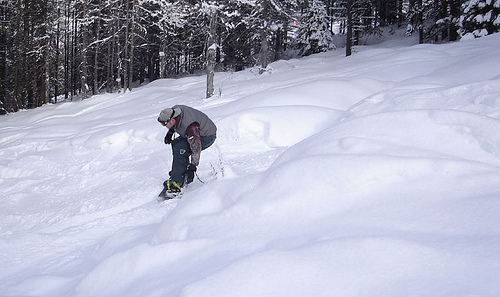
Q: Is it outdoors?
A: Yes, it is outdoors.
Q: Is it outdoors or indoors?
A: It is outdoors.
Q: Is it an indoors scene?
A: No, it is outdoors.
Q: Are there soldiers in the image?
A: No, there are no soldiers.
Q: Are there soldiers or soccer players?
A: No, there are no soldiers or soccer players.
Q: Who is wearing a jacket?
A: The man is wearing a jacket.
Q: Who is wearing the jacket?
A: The man is wearing a jacket.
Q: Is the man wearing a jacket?
A: Yes, the man is wearing a jacket.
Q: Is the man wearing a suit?
A: No, the man is wearing a jacket.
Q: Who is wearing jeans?
A: The man is wearing jeans.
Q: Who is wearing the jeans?
A: The man is wearing jeans.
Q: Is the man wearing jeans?
A: Yes, the man is wearing jeans.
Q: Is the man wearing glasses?
A: No, the man is wearing jeans.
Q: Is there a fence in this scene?
A: No, there are no fences.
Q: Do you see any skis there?
A: Yes, there are skis.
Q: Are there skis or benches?
A: Yes, there are skis.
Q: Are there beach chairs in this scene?
A: No, there are no beach chairs.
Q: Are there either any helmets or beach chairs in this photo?
A: No, there are no beach chairs or helmets.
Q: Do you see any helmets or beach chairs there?
A: No, there are no beach chairs or helmets.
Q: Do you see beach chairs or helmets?
A: No, there are no beach chairs or helmets.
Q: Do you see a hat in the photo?
A: Yes, there is a hat.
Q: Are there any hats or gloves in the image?
A: Yes, there is a hat.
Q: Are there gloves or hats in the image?
A: Yes, there is a hat.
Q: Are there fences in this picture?
A: No, there are no fences.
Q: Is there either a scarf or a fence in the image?
A: No, there are no fences or scarves.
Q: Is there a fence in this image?
A: No, there are no fences.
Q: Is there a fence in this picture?
A: No, there are no fences.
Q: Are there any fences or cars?
A: No, there are no fences or cars.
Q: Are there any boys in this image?
A: No, there are no boys.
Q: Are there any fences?
A: No, there are no fences.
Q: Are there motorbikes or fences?
A: No, there are no fences or motorbikes.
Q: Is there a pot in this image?
A: No, there are no pots.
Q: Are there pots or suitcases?
A: No, there are no pots or suitcases.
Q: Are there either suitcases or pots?
A: No, there are no pots or suitcases.